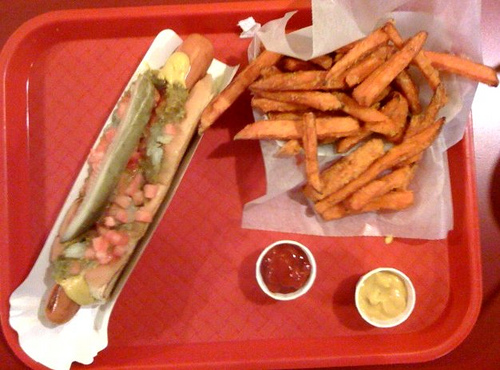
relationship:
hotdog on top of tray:
[58, 34, 220, 360] [2, 11, 499, 369]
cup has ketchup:
[253, 228, 318, 303] [273, 253, 299, 281]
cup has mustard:
[353, 261, 416, 334] [375, 283, 396, 321]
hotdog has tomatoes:
[58, 34, 220, 360] [101, 206, 139, 252]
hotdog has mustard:
[58, 34, 220, 360] [162, 48, 196, 87]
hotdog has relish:
[58, 34, 220, 360] [165, 89, 187, 120]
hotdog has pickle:
[58, 34, 220, 360] [57, 81, 156, 241]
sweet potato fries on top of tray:
[237, 29, 442, 143] [2, 11, 499, 369]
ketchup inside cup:
[273, 253, 299, 281] [253, 228, 318, 303]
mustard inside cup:
[375, 283, 396, 321] [353, 261, 416, 334]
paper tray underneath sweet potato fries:
[236, 20, 458, 225] [237, 29, 442, 143]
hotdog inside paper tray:
[58, 34, 220, 360] [31, 24, 226, 360]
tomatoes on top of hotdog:
[101, 206, 139, 252] [58, 34, 220, 360]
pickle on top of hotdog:
[57, 81, 156, 241] [58, 34, 220, 360]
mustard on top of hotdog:
[375, 283, 396, 321] [58, 34, 220, 360]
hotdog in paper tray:
[58, 34, 220, 360] [31, 24, 226, 360]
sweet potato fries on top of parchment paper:
[237, 29, 442, 143] [307, 1, 483, 151]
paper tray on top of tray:
[236, 20, 458, 225] [2, 11, 499, 369]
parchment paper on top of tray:
[307, 1, 483, 151] [2, 11, 499, 369]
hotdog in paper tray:
[58, 34, 220, 360] [3, 25, 243, 363]